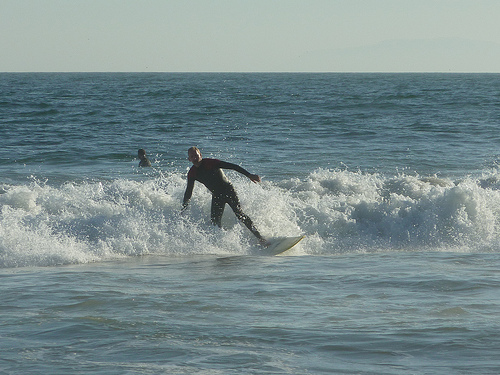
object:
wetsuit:
[183, 157, 263, 238]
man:
[179, 146, 269, 247]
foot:
[258, 238, 270, 246]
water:
[1, 73, 498, 373]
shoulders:
[187, 166, 195, 178]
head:
[187, 146, 201, 164]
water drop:
[169, 162, 174, 167]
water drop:
[205, 136, 210, 138]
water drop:
[237, 162, 242, 166]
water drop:
[243, 130, 247, 133]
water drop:
[228, 154, 233, 157]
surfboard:
[251, 235, 306, 256]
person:
[138, 149, 151, 168]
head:
[137, 149, 145, 160]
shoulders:
[141, 157, 147, 161]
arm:
[182, 176, 195, 207]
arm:
[216, 160, 247, 174]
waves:
[0, 164, 499, 268]